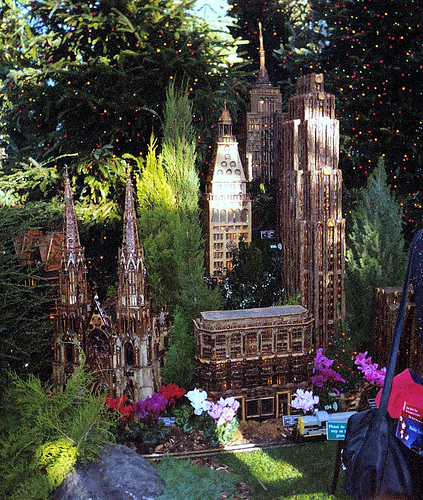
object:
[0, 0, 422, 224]
beads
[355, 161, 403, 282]
tree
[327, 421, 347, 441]
sign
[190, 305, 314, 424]
building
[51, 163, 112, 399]
building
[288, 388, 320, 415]
flowers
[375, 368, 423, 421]
bag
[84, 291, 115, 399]
buildings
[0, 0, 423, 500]
outside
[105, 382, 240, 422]
flowers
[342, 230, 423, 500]
purse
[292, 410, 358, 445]
train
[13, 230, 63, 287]
building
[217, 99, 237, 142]
tower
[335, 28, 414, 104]
lights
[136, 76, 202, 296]
tree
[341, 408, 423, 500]
bag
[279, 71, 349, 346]
building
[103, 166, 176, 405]
building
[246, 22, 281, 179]
building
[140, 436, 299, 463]
track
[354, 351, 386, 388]
flowers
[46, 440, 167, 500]
rock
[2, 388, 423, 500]
ground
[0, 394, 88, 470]
leaves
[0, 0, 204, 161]
tree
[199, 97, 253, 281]
building